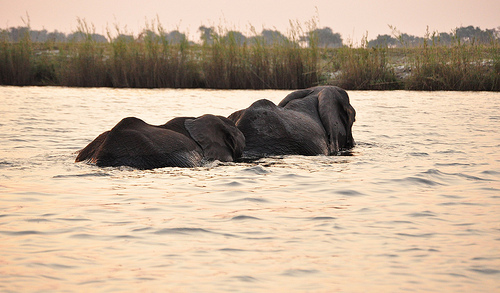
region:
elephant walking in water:
[0, 105, 126, 159]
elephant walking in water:
[238, 79, 357, 167]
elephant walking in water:
[72, 91, 227, 173]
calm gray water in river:
[17, 95, 57, 120]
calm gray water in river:
[17, 140, 53, 167]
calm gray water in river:
[32, 201, 129, 241]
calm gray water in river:
[148, 184, 217, 223]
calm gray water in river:
[274, 201, 344, 279]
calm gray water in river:
[382, 178, 466, 262]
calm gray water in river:
[374, 107, 454, 176]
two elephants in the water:
[74, 86, 356, 166]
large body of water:
[3, 92, 497, 289]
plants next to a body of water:
[0, 16, 495, 90]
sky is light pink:
[0, 0, 499, 45]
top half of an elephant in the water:
[224, 86, 355, 158]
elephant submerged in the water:
[72, 114, 247, 177]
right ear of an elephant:
[182, 116, 241, 163]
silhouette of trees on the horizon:
[4, 25, 497, 41]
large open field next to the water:
[0, 46, 497, 63]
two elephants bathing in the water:
[76, 86, 360, 166]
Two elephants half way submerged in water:
[70, 81, 370, 188]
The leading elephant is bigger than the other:
[69, 61, 358, 189]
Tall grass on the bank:
[7, 13, 432, 93]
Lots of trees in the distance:
[6, 16, 493, 53]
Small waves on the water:
[17, 167, 492, 289]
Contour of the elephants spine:
[66, 109, 207, 176]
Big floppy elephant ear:
[180, 113, 254, 169]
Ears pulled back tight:
[276, 81, 361, 162]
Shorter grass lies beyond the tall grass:
[10, 38, 499, 73]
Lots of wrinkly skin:
[226, 105, 318, 158]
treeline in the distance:
[1, 25, 499, 47]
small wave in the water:
[356, 164, 451, 208]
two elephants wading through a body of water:
[70, 80, 360, 175]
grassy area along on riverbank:
[0, 27, 499, 89]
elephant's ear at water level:
[184, 112, 249, 164]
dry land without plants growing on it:
[391, 49, 418, 75]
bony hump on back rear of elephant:
[228, 95, 290, 137]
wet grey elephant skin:
[310, 128, 350, 155]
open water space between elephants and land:
[365, 88, 498, 154]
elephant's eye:
[343, 102, 358, 129]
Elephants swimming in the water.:
[82, 48, 389, 188]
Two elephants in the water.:
[90, 58, 381, 197]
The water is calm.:
[93, 189, 427, 287]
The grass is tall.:
[108, 18, 290, 94]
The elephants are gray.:
[110, 70, 392, 169]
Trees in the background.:
[82, 8, 417, 63]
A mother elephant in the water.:
[248, 70, 375, 165]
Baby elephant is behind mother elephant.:
[98, 65, 365, 182]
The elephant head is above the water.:
[308, 78, 363, 153]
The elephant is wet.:
[88, 109, 240, 172]